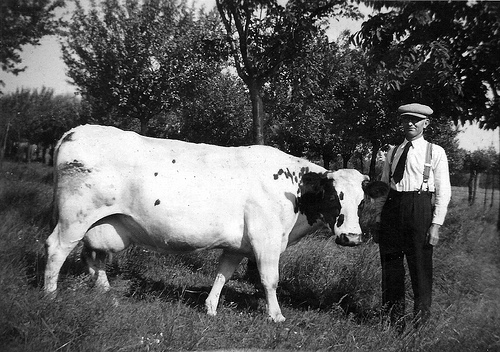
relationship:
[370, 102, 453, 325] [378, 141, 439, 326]
man wearing suspenders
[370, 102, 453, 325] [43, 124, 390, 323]
man by cow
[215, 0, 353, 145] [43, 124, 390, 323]
tree behind cow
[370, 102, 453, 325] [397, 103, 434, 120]
man wearing hat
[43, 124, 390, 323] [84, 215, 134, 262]
cow has udders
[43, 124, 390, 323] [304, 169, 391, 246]
cow has head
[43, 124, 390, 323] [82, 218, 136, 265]
cow has udder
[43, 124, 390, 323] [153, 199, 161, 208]
cow has spot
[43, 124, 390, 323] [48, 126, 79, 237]
cow has tail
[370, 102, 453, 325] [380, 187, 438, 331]
man wear pants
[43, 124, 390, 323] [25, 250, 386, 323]
cow has shadow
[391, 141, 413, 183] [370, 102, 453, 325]
tie on man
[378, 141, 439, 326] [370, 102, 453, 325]
suspenders on man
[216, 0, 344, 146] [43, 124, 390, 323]
trunk by cow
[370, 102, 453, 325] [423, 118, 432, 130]
man has ear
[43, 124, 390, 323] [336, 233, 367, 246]
cow has nose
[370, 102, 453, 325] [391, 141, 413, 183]
man has tie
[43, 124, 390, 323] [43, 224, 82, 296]
cow has leg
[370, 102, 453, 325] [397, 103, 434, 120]
man has hat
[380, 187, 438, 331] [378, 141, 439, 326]
pants on suspenders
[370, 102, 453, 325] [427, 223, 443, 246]
man has hand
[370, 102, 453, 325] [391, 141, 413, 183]
man wearing tie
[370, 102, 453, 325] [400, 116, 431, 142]
man has face